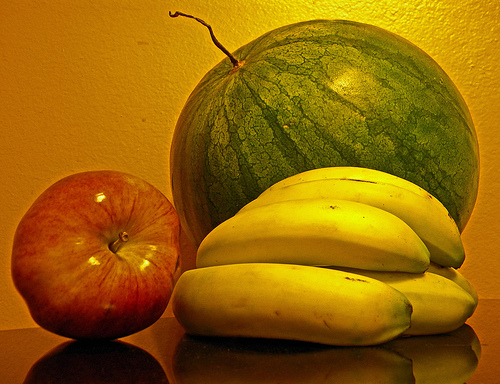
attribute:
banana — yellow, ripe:
[171, 244, 420, 360]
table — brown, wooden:
[1, 307, 495, 374]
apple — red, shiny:
[6, 164, 188, 345]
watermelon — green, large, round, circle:
[160, 10, 484, 223]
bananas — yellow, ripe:
[174, 164, 481, 347]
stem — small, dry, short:
[100, 221, 136, 257]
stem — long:
[168, 9, 255, 74]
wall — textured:
[7, 11, 495, 182]